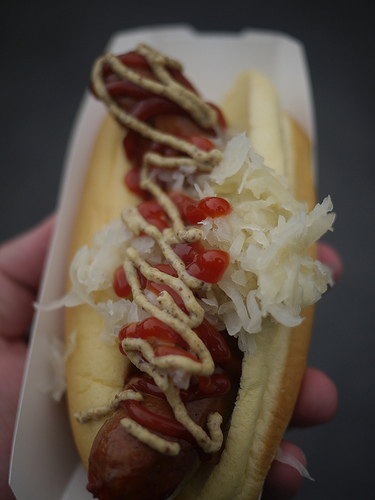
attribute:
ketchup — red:
[129, 167, 232, 227]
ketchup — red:
[110, 238, 230, 291]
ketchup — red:
[117, 317, 235, 395]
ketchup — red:
[121, 376, 215, 460]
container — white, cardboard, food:
[0, 30, 328, 492]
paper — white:
[7, 18, 321, 496]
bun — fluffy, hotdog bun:
[226, 95, 319, 487]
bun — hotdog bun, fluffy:
[65, 142, 126, 431]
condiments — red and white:
[115, 74, 258, 372]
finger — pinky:
[303, 362, 346, 441]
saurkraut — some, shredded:
[233, 190, 332, 334]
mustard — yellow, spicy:
[107, 242, 227, 396]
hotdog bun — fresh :
[75, 129, 136, 428]